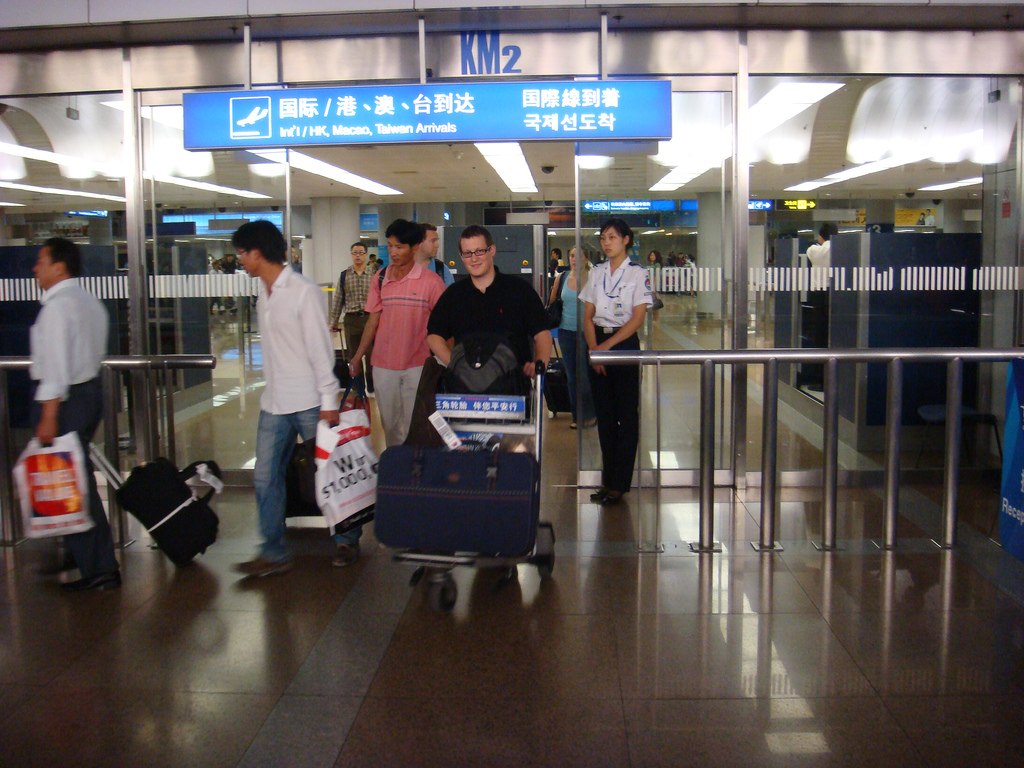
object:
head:
[458, 223, 497, 276]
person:
[345, 216, 444, 445]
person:
[419, 227, 554, 574]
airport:
[0, 0, 1024, 767]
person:
[575, 219, 655, 503]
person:
[328, 242, 380, 398]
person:
[25, 235, 126, 595]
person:
[227, 219, 359, 581]